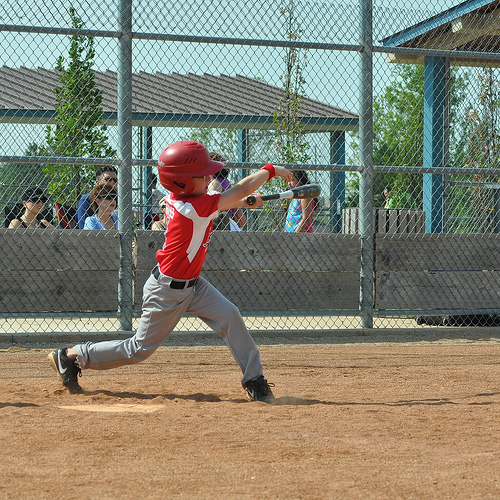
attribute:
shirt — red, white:
[156, 193, 222, 280]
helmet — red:
[157, 142, 227, 195]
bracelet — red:
[259, 162, 277, 180]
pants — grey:
[73, 263, 264, 386]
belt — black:
[151, 263, 200, 290]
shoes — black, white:
[46, 347, 278, 405]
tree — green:
[43, 0, 117, 209]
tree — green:
[375, 63, 465, 209]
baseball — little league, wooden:
[245, 178, 328, 212]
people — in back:
[7, 154, 317, 229]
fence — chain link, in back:
[1, 4, 499, 333]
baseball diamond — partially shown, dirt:
[57, 345, 489, 490]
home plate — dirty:
[54, 401, 169, 415]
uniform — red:
[80, 193, 264, 381]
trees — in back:
[7, 19, 497, 203]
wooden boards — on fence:
[1, 231, 499, 315]